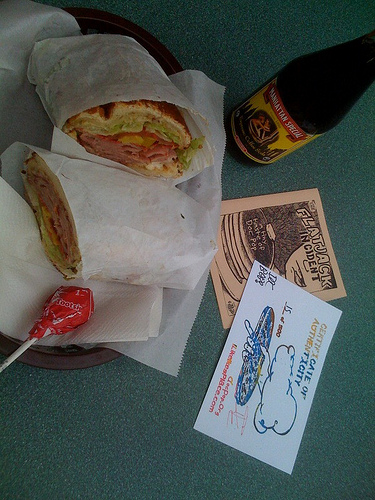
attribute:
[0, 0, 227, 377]
paper — white 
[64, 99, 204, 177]
sandwich — under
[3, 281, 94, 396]
tootsie pop — red tootsie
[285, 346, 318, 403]
letters — blue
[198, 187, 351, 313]
paper —  tan piece 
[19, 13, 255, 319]
sandwich — halved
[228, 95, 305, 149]
label — yellow, bottle 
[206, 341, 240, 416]
letters — red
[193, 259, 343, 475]
card — white business 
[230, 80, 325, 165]
label —  red , yellow, brown, Red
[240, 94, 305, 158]
label — yellow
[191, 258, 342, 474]
paper — white piece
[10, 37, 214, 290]
cut sandwich — cut into two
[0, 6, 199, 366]
serving basket — brown serving 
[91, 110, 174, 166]
sandwich — two halves 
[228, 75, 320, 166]
label — red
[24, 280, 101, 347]
red paper —  red 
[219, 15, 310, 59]
table — green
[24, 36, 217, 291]
sandwich — ham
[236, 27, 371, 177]
bottle —  drink 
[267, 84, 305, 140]
writing — white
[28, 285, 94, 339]
wrapper — red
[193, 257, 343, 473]
certificate — white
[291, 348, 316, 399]
writing — blue